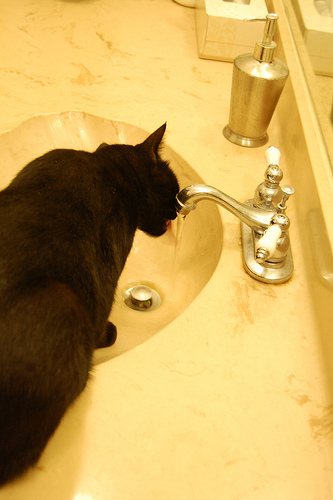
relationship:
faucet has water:
[196, 154, 322, 248] [176, 213, 202, 254]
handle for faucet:
[249, 140, 282, 190] [175, 135, 306, 288]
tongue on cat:
[167, 218, 185, 235] [0, 120, 181, 487]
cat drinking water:
[0, 120, 181, 487] [171, 209, 186, 275]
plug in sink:
[129, 284, 156, 307] [2, 108, 223, 364]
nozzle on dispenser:
[244, 14, 274, 41] [219, 14, 290, 146]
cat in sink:
[0, 120, 181, 487] [2, 108, 223, 364]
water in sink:
[171, 210, 190, 294] [2, 108, 223, 364]